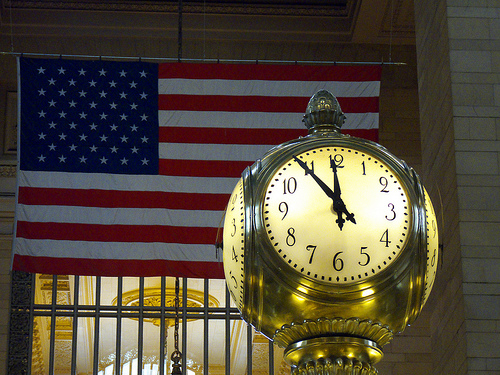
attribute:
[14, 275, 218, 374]
window — glass 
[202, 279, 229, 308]
window — glass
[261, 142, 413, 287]
clock — silver, shiny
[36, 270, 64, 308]
window — glass 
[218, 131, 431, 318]
clock — white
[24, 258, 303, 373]
bars — silver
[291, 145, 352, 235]
hands — hour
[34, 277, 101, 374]
window — glass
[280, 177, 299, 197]
number — black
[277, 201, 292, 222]
number — black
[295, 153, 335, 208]
minute — black